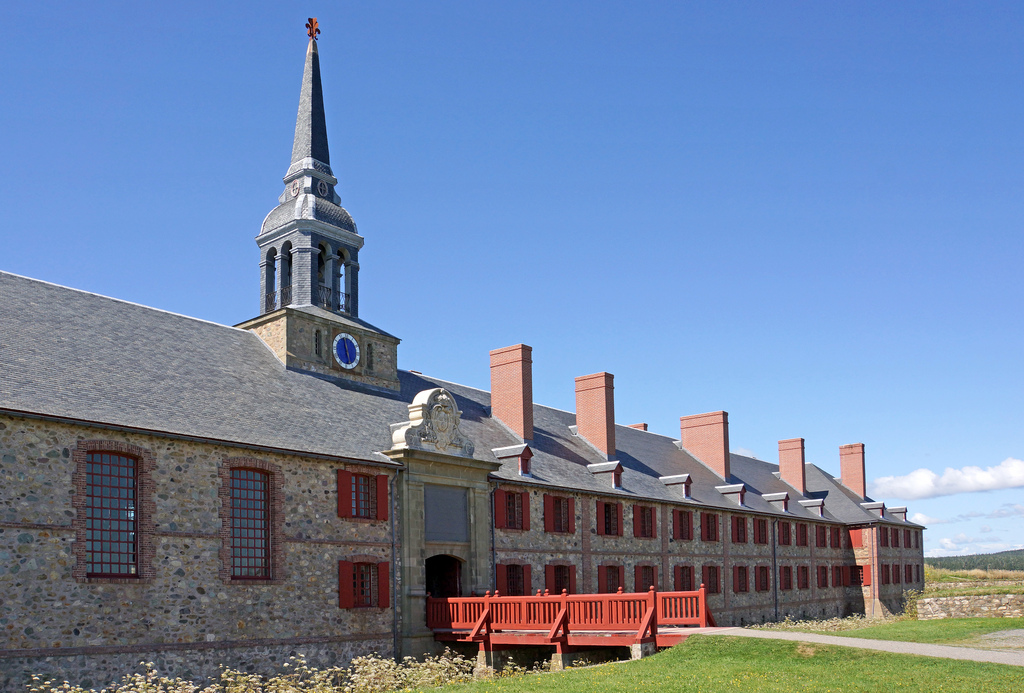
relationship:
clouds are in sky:
[876, 451, 1018, 509] [2, 2, 1022, 545]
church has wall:
[0, 17, 924, 690] [911, 581, 1022, 625]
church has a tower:
[0, 17, 924, 690] [259, 17, 381, 322]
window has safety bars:
[65, 434, 150, 582] [84, 456, 139, 567]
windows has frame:
[217, 454, 282, 585] [214, 453, 277, 601]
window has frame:
[337, 557, 392, 612] [326, 550, 396, 613]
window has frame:
[65, 437, 149, 582] [65, 442, 169, 587]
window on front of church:
[493, 483, 533, 538] [9, 28, 917, 690]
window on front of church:
[482, 553, 530, 593] [9, 28, 917, 690]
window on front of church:
[545, 561, 578, 601] [9, 28, 917, 690]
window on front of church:
[598, 501, 631, 538] [9, 28, 917, 690]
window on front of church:
[594, 557, 631, 597] [9, 28, 917, 690]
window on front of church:
[624, 509, 661, 538] [9, 28, 917, 690]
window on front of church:
[631, 557, 664, 601] [9, 28, 917, 690]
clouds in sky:
[683, 386, 1021, 512] [2, 2, 1022, 545]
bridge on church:
[439, 575, 710, 660] [0, 17, 924, 690]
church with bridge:
[0, 17, 924, 690] [439, 575, 710, 660]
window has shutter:
[345, 469, 376, 521] [332, 469, 358, 521]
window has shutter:
[345, 469, 376, 521] [371, 475, 391, 517]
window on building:
[345, 469, 376, 521] [6, 270, 927, 692]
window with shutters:
[493, 483, 533, 534] [485, 484, 538, 534]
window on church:
[493, 483, 533, 534] [0, 17, 924, 690]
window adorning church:
[353, 562, 382, 610] [0, 17, 924, 690]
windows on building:
[166, 432, 309, 599] [30, 365, 748, 687]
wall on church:
[11, 407, 411, 680] [0, 17, 924, 690]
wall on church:
[0, 402, 414, 680] [0, 17, 924, 690]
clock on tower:
[330, 325, 365, 378] [244, 5, 430, 377]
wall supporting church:
[0, 402, 414, 680] [0, 17, 924, 690]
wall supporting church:
[11, 407, 411, 680] [0, 17, 924, 690]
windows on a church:
[217, 454, 282, 585] [0, 17, 924, 690]